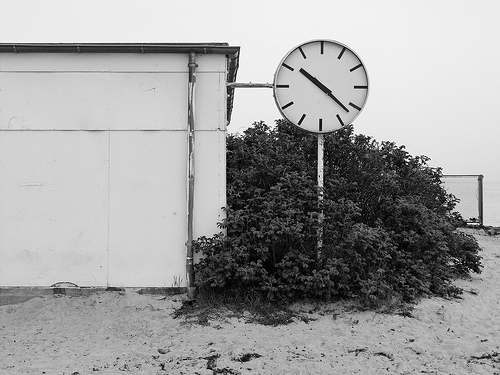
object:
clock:
[269, 38, 372, 137]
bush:
[188, 121, 482, 309]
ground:
[0, 229, 498, 375]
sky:
[1, 0, 495, 174]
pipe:
[183, 52, 194, 300]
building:
[0, 42, 242, 288]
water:
[436, 178, 499, 227]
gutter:
[0, 35, 243, 48]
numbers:
[287, 54, 359, 116]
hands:
[296, 63, 352, 114]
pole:
[316, 133, 327, 277]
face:
[287, 57, 354, 122]